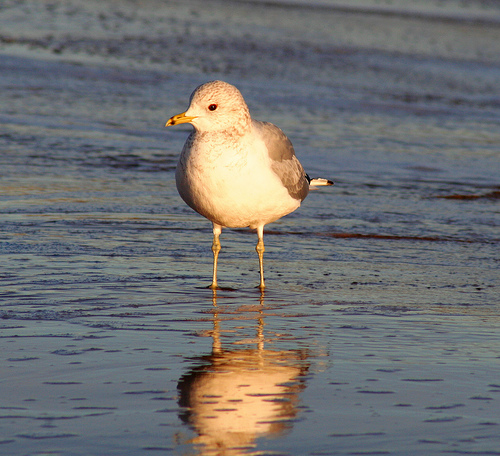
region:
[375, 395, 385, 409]
part of the sea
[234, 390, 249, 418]
part of a shadow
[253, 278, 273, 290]
leg of a bird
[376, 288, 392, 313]
part of the sea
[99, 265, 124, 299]
part of the lake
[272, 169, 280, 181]
body of a bird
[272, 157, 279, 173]
feather of a bird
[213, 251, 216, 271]
leg of a bird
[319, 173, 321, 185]
part of a feather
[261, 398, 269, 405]
shadow of a feather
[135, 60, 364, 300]
a seagull at the ocean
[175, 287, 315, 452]
the reflection of a seagull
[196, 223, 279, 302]
the legs on a seagull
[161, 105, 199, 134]
the bill on a seagull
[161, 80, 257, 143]
the head on a seagull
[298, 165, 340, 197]
the tail on a seagull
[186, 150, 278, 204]
the breast on a seagull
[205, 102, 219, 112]
the eye on a seagull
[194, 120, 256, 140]
the neck on a seagull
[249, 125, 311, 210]
the wing on a seagull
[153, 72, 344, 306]
the gull is standing in shallow water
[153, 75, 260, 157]
the spotty head pattern indicates an immature individual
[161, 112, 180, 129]
the bill marking is useful in identifying the species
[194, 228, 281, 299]
the legs are yellowish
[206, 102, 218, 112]
the eye is black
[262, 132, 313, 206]
the top of the flight feathers are grey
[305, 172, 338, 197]
the tail is white with a black tip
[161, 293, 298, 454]
a reflection of the gull on the water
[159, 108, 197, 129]
the bill is yellow with a black mark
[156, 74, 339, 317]
the gull is searching for food in the surf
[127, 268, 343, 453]
a reflection in water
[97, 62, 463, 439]
a bird standing in water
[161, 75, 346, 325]
a yellow beak on a bird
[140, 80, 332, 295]
a bird looking to its right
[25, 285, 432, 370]
ripples in the water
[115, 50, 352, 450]
a bird's reflection in the water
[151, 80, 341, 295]
a bird standing in water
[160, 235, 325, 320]
bird legs in the water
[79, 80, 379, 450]
a bird is being reflected in the water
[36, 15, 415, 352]
a body of water surrounds the bird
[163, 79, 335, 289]
a white and gray bird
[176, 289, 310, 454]
a reflection of a bird on the water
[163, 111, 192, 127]
a bird's yellow beak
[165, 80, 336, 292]
a bird with a yellow beak standing in the water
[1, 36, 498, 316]
a bird standing in water on the beach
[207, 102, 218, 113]
the bird's left eye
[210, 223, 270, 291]
the bird's two legs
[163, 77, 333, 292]
a gray and white bird standing in the water on a beach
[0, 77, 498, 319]
a bird looking at something while standing in the water